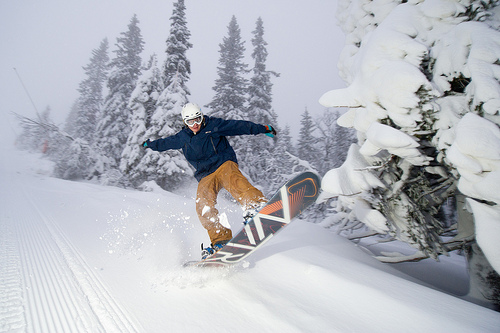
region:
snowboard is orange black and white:
[161, 179, 330, 287]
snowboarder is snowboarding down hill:
[128, 86, 320, 261]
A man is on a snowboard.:
[133, 96, 340, 286]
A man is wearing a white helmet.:
[175, 98, 208, 135]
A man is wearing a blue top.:
[134, 113, 280, 185]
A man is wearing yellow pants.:
[188, 158, 273, 255]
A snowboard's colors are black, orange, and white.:
[178, 163, 330, 283]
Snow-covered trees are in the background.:
[3, 0, 322, 202]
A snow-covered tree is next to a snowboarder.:
[310, 0, 498, 320]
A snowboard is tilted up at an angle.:
[179, 164, 325, 284]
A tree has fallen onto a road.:
[0, 56, 128, 203]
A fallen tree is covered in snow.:
[1, 64, 118, 202]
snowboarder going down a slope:
[88, 75, 358, 303]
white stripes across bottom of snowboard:
[115, 155, 356, 272]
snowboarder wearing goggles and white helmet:
[151, 95, 221, 140]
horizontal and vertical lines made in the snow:
[1, 170, 111, 325]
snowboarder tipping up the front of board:
[126, 95, 341, 290]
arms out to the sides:
[131, 111, 291, 163]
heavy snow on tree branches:
[316, 47, 466, 267]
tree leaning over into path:
[5, 77, 125, 187]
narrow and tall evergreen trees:
[76, 10, 176, 185]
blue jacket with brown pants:
[138, 105, 293, 240]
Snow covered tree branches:
[319, 47, 462, 157]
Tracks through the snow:
[26, 164, 156, 322]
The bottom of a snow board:
[191, 170, 308, 297]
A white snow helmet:
[172, 92, 214, 132]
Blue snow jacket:
[121, 120, 278, 168]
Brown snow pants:
[187, 178, 261, 253]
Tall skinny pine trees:
[86, 20, 200, 198]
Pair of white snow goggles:
[176, 117, 211, 128]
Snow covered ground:
[35, 193, 402, 302]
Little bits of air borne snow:
[73, 189, 249, 261]